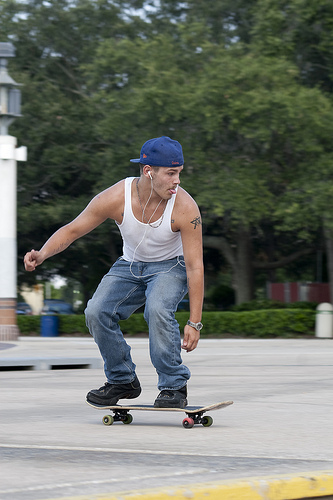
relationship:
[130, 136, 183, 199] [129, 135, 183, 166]
head wearing hat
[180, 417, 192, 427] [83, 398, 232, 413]
wheel on board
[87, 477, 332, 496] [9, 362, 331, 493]
yellow paint on sidewalk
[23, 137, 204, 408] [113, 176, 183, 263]
boy wearing shirt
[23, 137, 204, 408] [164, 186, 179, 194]
boy sticking out h tongue